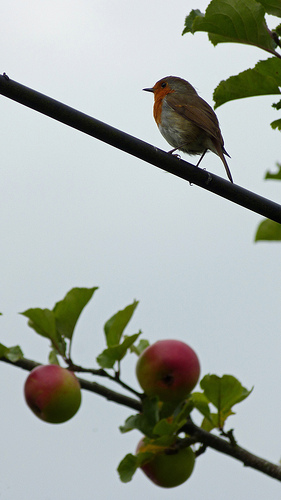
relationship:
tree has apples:
[2, 3, 279, 500] [23, 330, 201, 489]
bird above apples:
[137, 65, 237, 212] [23, 330, 201, 489]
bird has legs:
[137, 65, 237, 212] [163, 129, 212, 186]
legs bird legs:
[196, 148, 207, 166] [163, 129, 212, 186]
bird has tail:
[137, 65, 237, 212] [207, 137, 236, 188]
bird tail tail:
[137, 65, 237, 212] [207, 137, 236, 188]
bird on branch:
[137, 65, 237, 212] [0, 74, 281, 225]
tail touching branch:
[207, 137, 236, 188] [0, 74, 281, 225]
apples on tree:
[23, 330, 201, 489] [2, 3, 279, 500]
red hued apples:
[21, 341, 200, 427] [23, 330, 201, 489]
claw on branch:
[139, 133, 225, 204] [0, 74, 281, 225]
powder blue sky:
[32, 154, 135, 256] [12, 3, 167, 61]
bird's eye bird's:
[156, 80, 170, 90] [161, 81, 165, 87]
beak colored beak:
[142, 88, 153, 92] [140, 83, 163, 97]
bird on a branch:
[137, 65, 237, 212] [0, 83, 265, 198]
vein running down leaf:
[212, 376, 226, 438] [202, 372, 247, 428]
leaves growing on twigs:
[1, 266, 269, 484] [67, 360, 129, 386]